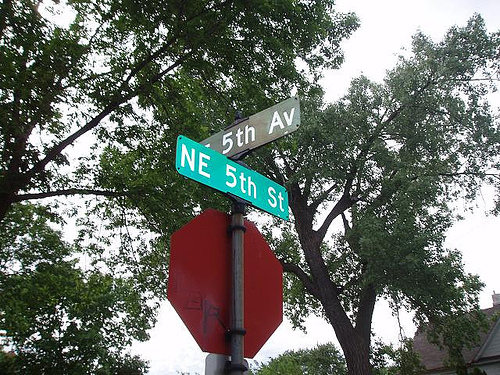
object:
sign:
[168, 84, 275, 203]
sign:
[166, 227, 272, 335]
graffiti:
[179, 298, 250, 356]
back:
[150, 238, 268, 364]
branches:
[64, 38, 233, 185]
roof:
[406, 323, 488, 369]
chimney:
[468, 289, 497, 301]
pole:
[224, 232, 273, 361]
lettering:
[170, 135, 298, 211]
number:
[219, 165, 244, 188]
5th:
[206, 161, 283, 209]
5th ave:
[207, 117, 329, 160]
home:
[384, 287, 480, 370]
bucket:
[482, 289, 500, 303]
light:
[321, 38, 367, 77]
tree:
[20, 44, 165, 363]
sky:
[148, 325, 192, 373]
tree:
[297, 80, 445, 360]